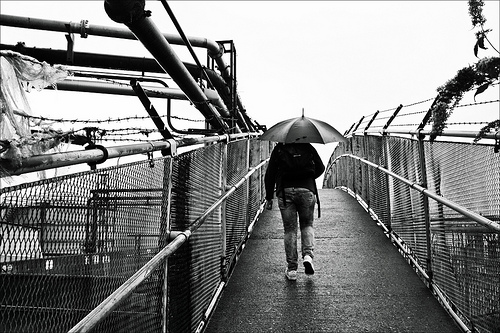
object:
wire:
[18, 111, 151, 124]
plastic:
[0, 48, 68, 166]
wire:
[72, 72, 169, 88]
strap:
[315, 193, 321, 218]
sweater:
[264, 140, 326, 201]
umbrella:
[256, 107, 348, 146]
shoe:
[302, 255, 315, 276]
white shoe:
[284, 266, 298, 281]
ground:
[220, 186, 470, 333]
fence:
[2, 131, 270, 331]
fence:
[322, 92, 498, 331]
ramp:
[216, 185, 458, 333]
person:
[264, 129, 326, 281]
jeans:
[274, 188, 319, 271]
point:
[301, 107, 304, 117]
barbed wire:
[123, 18, 229, 133]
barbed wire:
[402, 96, 437, 108]